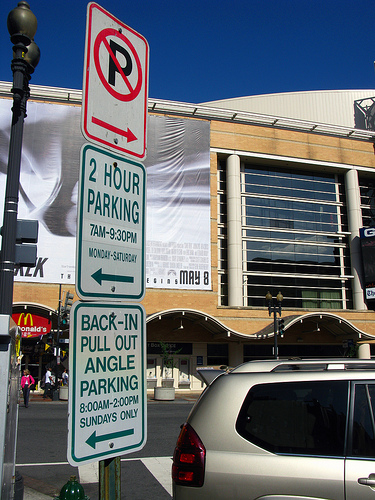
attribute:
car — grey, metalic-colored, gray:
[171, 356, 374, 499]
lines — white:
[0, 453, 178, 499]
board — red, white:
[81, 1, 150, 161]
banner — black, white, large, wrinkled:
[0, 97, 214, 293]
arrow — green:
[89, 267, 135, 288]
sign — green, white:
[76, 143, 146, 301]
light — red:
[170, 421, 208, 487]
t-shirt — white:
[43, 370, 52, 384]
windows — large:
[217, 158, 374, 311]